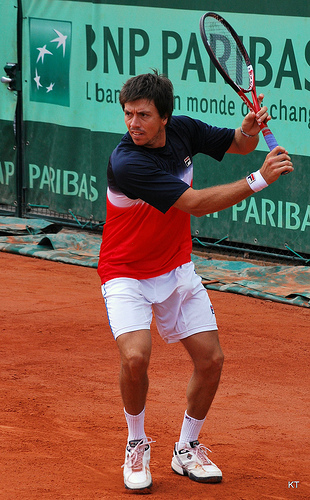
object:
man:
[97, 66, 294, 495]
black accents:
[125, 438, 143, 452]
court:
[0, 252, 310, 499]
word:
[162, 29, 310, 92]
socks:
[122, 407, 147, 445]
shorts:
[100, 260, 219, 345]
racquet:
[200, 12, 293, 176]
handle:
[254, 106, 292, 175]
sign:
[0, 0, 310, 262]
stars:
[49, 28, 67, 59]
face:
[123, 98, 161, 146]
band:
[244, 169, 268, 192]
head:
[118, 69, 174, 146]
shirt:
[96, 115, 236, 287]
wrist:
[254, 170, 265, 192]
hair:
[138, 78, 162, 91]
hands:
[260, 145, 295, 187]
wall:
[0, 0, 310, 171]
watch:
[239, 125, 259, 142]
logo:
[182, 153, 191, 167]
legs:
[96, 263, 157, 491]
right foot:
[119, 435, 157, 493]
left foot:
[171, 438, 223, 483]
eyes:
[124, 110, 133, 118]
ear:
[161, 112, 168, 127]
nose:
[131, 112, 140, 128]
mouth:
[129, 129, 144, 135]